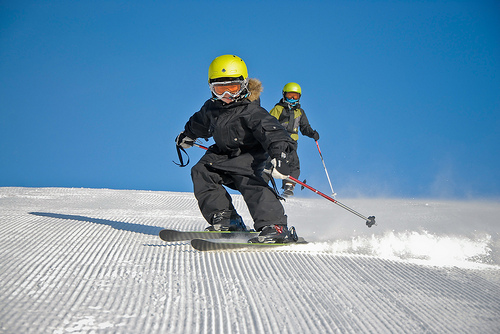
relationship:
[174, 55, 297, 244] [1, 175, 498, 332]
child skiing down mountainside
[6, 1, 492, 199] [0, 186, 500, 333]
sky above hill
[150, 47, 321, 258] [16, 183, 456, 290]
child snowboarding down hill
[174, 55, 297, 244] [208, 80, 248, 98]
child wears goggles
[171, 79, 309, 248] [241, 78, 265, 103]
coat has hood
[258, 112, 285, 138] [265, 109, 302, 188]
pocket on sleeve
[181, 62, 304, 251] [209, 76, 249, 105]
child wearing goggles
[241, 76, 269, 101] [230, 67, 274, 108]
fur around hood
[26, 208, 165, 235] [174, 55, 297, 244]
shadow of a child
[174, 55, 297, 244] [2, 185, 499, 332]
child on snow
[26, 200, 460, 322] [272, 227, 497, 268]
lines in sfresh snow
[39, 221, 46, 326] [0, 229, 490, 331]
ridge throughout snow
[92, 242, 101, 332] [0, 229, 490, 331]
ridge throughout snow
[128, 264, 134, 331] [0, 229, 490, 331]
ridge throughout snow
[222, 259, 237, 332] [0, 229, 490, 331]
ridge throughout snow